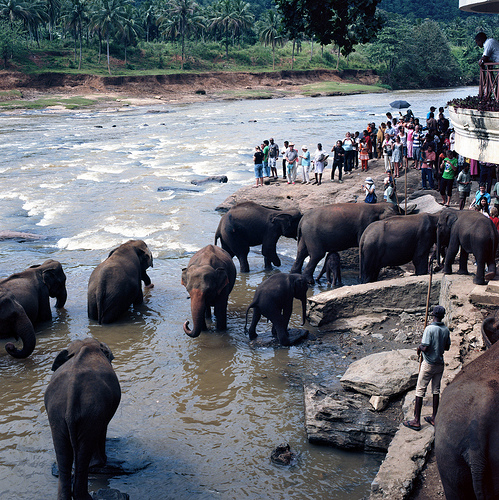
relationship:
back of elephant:
[48, 342, 107, 410] [30, 332, 157, 483]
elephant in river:
[179, 243, 237, 339] [0, 85, 485, 497]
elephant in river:
[52, 321, 137, 481] [0, 85, 485, 497]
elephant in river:
[296, 183, 378, 273] [0, 85, 485, 497]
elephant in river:
[213, 200, 303, 274] [0, 85, 485, 497]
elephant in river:
[87, 237, 155, 326] [0, 85, 485, 497]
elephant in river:
[44, 336, 120, 496] [0, 85, 485, 497]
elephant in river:
[0, 283, 38, 361] [0, 85, 485, 497]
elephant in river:
[0, 257, 68, 341] [0, 85, 485, 497]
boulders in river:
[315, 272, 483, 499] [0, 85, 485, 497]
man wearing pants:
[403, 304, 452, 432] [416, 359, 446, 399]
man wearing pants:
[434, 146, 462, 207] [416, 359, 446, 399]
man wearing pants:
[474, 32, 499, 99] [416, 359, 446, 399]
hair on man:
[427, 304, 447, 316] [407, 301, 461, 431]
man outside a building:
[474, 32, 499, 99] [445, 1, 497, 167]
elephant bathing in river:
[179, 243, 237, 339] [0, 85, 485, 497]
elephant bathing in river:
[84, 231, 162, 310] [0, 85, 485, 497]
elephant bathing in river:
[214, 190, 300, 266] [0, 85, 485, 497]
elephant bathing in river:
[3, 258, 74, 325] [0, 85, 485, 497]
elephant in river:
[43, 335, 123, 500] [0, 85, 485, 497]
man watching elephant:
[474, 32, 499, 99] [241, 272, 308, 347]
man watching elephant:
[474, 32, 499, 99] [179, 245, 237, 344]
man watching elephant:
[474, 32, 499, 99] [87, 237, 155, 326]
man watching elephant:
[474, 32, 499, 99] [44, 336, 120, 496]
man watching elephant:
[474, 32, 499, 99] [2, 260, 66, 361]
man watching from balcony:
[474, 32, 499, 99] [446, 98, 495, 168]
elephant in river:
[241, 272, 308, 347] [8, 124, 189, 223]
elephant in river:
[179, 245, 237, 344] [8, 124, 189, 223]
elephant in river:
[87, 237, 155, 326] [8, 124, 189, 223]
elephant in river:
[44, 336, 120, 496] [8, 124, 189, 223]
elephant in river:
[2, 260, 66, 361] [8, 124, 189, 223]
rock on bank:
[324, 344, 438, 439] [248, 133, 447, 456]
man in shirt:
[401, 304, 452, 432] [418, 324, 450, 362]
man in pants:
[401, 304, 452, 432] [406, 356, 445, 397]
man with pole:
[401, 304, 452, 432] [415, 246, 441, 358]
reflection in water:
[179, 331, 241, 417] [4, 89, 386, 498]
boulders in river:
[269, 439, 296, 466] [0, 85, 485, 497]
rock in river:
[143, 120, 148, 128] [0, 85, 485, 497]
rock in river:
[160, 120, 165, 126] [0, 85, 485, 497]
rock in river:
[95, 123, 102, 128] [0, 85, 485, 497]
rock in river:
[111, 121, 117, 128] [0, 85, 485, 497]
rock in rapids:
[185, 163, 237, 195] [41, 129, 348, 252]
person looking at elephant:
[313, 139, 330, 184] [243, 270, 317, 351]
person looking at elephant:
[297, 142, 314, 186] [179, 245, 237, 344]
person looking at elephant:
[331, 139, 343, 181] [86, 237, 158, 323]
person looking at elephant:
[380, 174, 394, 201] [0, 256, 69, 323]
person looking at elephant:
[355, 135, 371, 172] [288, 200, 403, 282]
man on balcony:
[463, 28, 497, 82] [446, 84, 485, 98]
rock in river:
[384, 96, 413, 116] [0, 86, 431, 356]